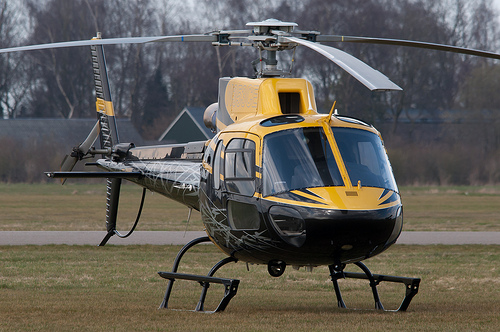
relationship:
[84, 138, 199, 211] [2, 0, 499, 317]
tail of helicopter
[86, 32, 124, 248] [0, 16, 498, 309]
tail on hellicopter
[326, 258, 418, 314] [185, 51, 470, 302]
leg of a helicopter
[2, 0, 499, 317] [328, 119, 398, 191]
helicopter has window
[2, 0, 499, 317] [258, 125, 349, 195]
helicopter has window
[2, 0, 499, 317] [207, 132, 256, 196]
helicopter has window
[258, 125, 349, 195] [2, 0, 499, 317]
window on helicopter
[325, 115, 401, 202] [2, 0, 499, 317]
window on helicopter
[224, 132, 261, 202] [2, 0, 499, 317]
window on helicopter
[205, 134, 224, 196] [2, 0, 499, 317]
window on helicopter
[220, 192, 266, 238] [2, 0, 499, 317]
window on helicopter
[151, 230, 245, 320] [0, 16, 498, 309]
leg on hellicopter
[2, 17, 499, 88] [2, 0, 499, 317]
wings on helicopter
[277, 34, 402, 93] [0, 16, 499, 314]
rotor on helicopter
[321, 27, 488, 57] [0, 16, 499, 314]
rotor on helicopter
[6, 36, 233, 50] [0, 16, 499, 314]
rotor on helicopter